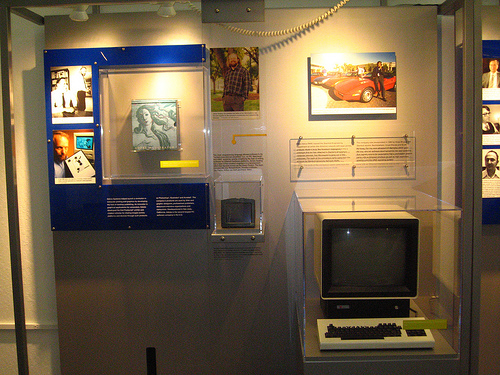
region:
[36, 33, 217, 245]
Display case hanging on the wall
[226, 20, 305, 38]
Yellow cord hanging from the ceiling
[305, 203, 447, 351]
Older model computer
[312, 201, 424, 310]
Older model computer monitor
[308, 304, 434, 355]
Older model computer keyboard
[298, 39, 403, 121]
Picture displayed on the wall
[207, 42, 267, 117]
Picture of a man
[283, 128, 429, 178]
Informational plate mounted on the wall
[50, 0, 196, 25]
Two lights mounted on the ceiling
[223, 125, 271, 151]
Yellow arrow pointing to information about the display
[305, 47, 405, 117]
The frame that has a red car pictured in it.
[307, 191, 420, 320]
The computer monitor in the case.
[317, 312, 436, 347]
The keyboard in front of the computer monitor.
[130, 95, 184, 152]
The black and white picture of a woman.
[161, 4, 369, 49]
The cream colored spiral wire above the exhibit.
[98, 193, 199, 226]
The white letters on the blue exhibit.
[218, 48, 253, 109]
The picture of the man in a plaid shirt.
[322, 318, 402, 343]
The black keys on the keyboard.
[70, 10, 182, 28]
The two white lights above the exhibit near the spiral wire cord.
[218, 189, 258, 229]
The small square black box to the right of the computer monitor.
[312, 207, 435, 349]
An old white and black computer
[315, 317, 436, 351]
An old white and black keyboard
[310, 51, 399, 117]
A photo of a person leaning on a red car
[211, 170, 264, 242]
An item on display inside a clear box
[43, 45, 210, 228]
A blue information display with white words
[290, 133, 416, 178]
An information plaque above a display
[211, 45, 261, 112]
A picture of a man wearing a plaid shirt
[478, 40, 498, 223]
The edge of a display with three pictures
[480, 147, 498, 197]
A black and white picture of a man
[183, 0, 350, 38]
A spiral white cord hanging down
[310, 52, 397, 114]
Picture hanging on the wall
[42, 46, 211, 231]
Display exhibit hanging on the wall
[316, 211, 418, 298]
Very old display monitor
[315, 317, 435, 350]
Very old computer keyboard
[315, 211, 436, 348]
Very old computer on display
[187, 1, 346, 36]
Flexible coiled electrical cord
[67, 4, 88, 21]
Spotlight hung from the ceiling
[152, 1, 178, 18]
Spotlight illuminating exhibit display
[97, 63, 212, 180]
Plexiglas box on the wall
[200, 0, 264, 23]
Brace securing large sheet of glass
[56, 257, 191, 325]
this is the wall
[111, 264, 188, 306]
the wall is white in color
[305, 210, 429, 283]
this is a screen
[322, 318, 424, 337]
thus is the keyboard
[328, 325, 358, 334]
the buttons are black in color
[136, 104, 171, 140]
this is a lady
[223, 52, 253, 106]
this is a man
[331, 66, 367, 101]
this is a car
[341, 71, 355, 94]
the car is red in color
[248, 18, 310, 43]
this is a cable